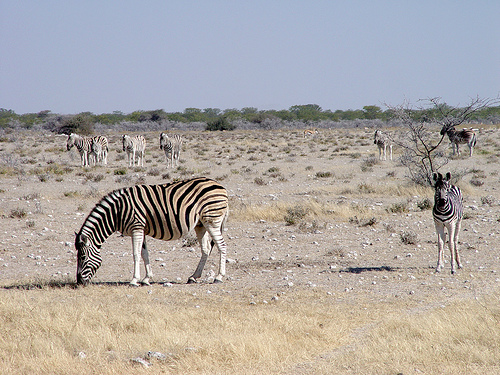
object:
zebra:
[432, 172, 465, 275]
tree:
[376, 92, 500, 188]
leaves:
[373, 103, 378, 113]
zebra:
[74, 176, 230, 288]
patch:
[34, 302, 47, 321]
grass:
[253, 203, 275, 219]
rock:
[251, 256, 259, 261]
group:
[67, 132, 184, 170]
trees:
[115, 109, 159, 130]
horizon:
[0, 66, 500, 114]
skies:
[37, 20, 483, 91]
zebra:
[440, 122, 477, 157]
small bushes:
[284, 199, 307, 216]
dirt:
[343, 235, 358, 251]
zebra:
[160, 132, 183, 169]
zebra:
[122, 134, 146, 167]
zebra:
[66, 133, 93, 168]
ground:
[318, 289, 426, 324]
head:
[74, 230, 103, 288]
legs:
[128, 228, 144, 288]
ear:
[78, 233, 89, 246]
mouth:
[82, 279, 90, 289]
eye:
[81, 256, 86, 260]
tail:
[221, 201, 230, 235]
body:
[104, 176, 229, 230]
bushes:
[203, 118, 235, 130]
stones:
[226, 258, 236, 263]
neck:
[86, 190, 117, 245]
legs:
[434, 224, 445, 274]